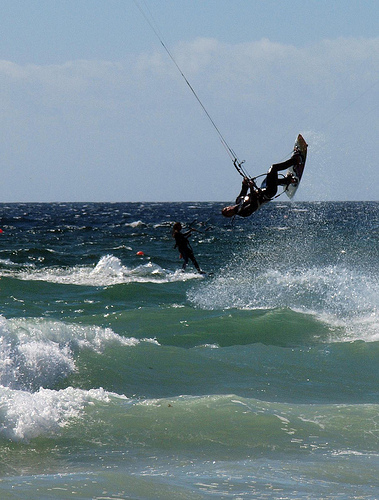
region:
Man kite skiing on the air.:
[219, 133, 312, 224]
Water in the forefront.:
[0, 201, 373, 493]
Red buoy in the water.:
[131, 246, 140, 254]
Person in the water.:
[163, 215, 204, 274]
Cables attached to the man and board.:
[116, 0, 246, 185]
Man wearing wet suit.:
[212, 130, 304, 216]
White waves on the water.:
[0, 307, 156, 444]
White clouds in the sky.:
[0, 32, 377, 106]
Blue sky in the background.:
[0, 0, 374, 196]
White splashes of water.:
[301, 124, 325, 171]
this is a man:
[218, 161, 294, 224]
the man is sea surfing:
[208, 152, 284, 225]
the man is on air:
[207, 141, 300, 224]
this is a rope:
[194, 107, 221, 136]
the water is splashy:
[282, 212, 345, 274]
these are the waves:
[37, 326, 160, 419]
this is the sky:
[33, 59, 138, 167]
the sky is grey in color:
[31, 49, 145, 164]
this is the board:
[297, 131, 311, 151]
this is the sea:
[88, 199, 151, 225]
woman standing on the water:
[152, 208, 212, 285]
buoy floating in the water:
[132, 248, 146, 257]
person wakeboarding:
[198, 121, 344, 243]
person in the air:
[195, 129, 330, 228]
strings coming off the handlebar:
[136, 3, 270, 188]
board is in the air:
[263, 122, 326, 230]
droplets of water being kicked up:
[190, 220, 378, 333]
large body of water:
[2, 203, 376, 499]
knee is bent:
[259, 160, 281, 174]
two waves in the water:
[0, 312, 373, 454]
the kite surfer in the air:
[214, 118, 319, 249]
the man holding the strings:
[239, 170, 256, 191]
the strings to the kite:
[126, 0, 245, 166]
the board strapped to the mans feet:
[281, 136, 309, 210]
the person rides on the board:
[165, 219, 217, 275]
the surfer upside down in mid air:
[215, 119, 316, 234]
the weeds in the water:
[161, 390, 181, 417]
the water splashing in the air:
[202, 222, 377, 320]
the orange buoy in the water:
[132, 248, 147, 260]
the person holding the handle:
[184, 221, 206, 237]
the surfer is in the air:
[213, 139, 329, 242]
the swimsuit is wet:
[237, 158, 291, 217]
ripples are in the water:
[103, 264, 337, 488]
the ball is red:
[136, 244, 151, 265]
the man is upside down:
[214, 153, 309, 221]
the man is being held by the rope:
[216, 117, 329, 235]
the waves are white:
[22, 338, 73, 410]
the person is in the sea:
[162, 219, 201, 268]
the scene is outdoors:
[2, 2, 369, 495]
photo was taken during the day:
[6, 3, 376, 497]